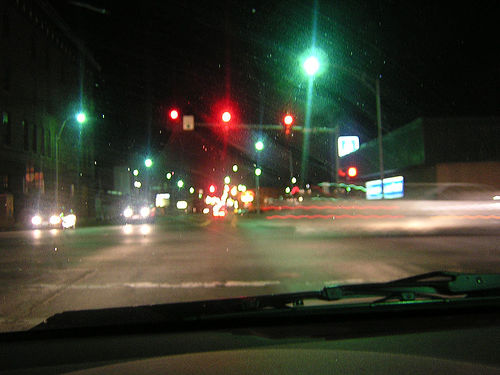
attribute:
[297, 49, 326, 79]
light — green, bright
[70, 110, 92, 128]
light — green, bright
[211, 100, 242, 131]
light — red, bright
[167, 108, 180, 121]
light — red, bright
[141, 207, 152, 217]
light — white, bright, on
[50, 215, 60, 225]
light — white, bright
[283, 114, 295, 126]
light — red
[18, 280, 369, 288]
line — white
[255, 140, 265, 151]
light — bright, green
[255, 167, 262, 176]
light — bright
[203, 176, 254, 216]
lights — bright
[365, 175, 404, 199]
sign — blue